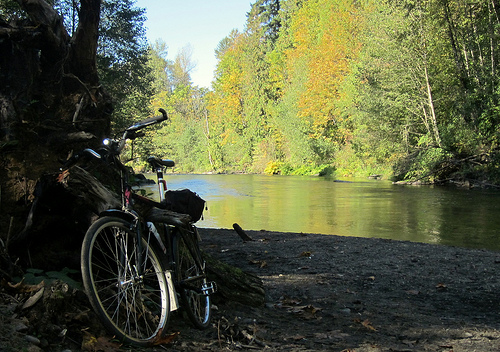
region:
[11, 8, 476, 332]
bike parked at lake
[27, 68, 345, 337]
bicycle parked at lake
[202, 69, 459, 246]
beautiful tree lined lake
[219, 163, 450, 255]
green trees and sunlight reflected in lake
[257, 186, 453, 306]
dirt bank of lake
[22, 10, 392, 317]
shady spot by the lake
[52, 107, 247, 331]
black bicycle parked by lake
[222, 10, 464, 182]
green and yellow trees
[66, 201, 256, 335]
bicycle with black tires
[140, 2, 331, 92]
clear blue sky behind trees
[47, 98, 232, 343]
two parked bicycles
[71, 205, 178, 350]
wheel on bicycle next to the lake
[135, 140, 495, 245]
lake filled with water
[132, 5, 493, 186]
trees surrounding the lake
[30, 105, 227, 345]
two bicycles by the lake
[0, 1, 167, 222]
an old brown tree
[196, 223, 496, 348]
dirt by the lake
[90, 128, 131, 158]
the bell on the bicycle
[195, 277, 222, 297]
pedal on bicycle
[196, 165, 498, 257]
water from the lake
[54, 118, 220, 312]
black bike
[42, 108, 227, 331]
black and silver bike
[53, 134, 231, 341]
black and silver bike leaning aginst tree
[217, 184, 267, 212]
calm water of river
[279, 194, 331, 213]
calm water of river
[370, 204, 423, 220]
calm water of river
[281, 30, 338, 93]
tree with green and orange leaves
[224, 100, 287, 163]
tree with green and orange leaves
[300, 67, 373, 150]
tree with green and orange leaves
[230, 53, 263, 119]
tree with green and orange leaves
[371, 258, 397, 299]
part of a bunk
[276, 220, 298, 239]
edge of a bunk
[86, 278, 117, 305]
part of a bike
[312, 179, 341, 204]
part of a river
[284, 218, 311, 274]
part of the soil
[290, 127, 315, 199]
part of a river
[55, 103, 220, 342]
gray and silver bicycle leaning on a tree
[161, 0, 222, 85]
treetops with pale and light blue sky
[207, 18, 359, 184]
green yellow and brown trees near water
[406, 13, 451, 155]
birch tree near water's edge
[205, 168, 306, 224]
green and yellow reflection of trees in the water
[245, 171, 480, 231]
sunny and shaded areas reflected on water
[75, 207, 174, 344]
black and silver front wheel of a bicycle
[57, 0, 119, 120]
large tree trunk growing out the side of a hill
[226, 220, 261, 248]
small tree stump sticking out of the dirt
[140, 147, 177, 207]
silver and black bicycle seat